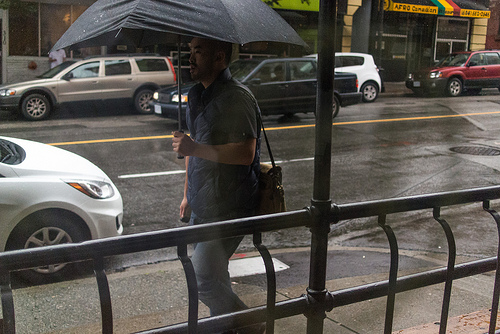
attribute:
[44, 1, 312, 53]
umbrella — black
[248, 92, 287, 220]
suitcase — brown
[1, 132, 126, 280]
car — white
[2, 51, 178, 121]
car — champagne colored, tan, parked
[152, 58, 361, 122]
car — black, passing by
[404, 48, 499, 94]
car — red, parked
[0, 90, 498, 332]
street — wet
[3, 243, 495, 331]
sidewalk — wet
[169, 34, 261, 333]
man — walking, asian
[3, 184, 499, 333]
fence — made of metal, black, metal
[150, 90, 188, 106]
car's lights — on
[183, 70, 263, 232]
shirt — short sleeve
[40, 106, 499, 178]
lines — yellow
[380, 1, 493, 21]
colorful awning — yellow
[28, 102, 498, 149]
line — yellow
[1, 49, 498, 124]
vehicles — parked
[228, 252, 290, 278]
lid — metal